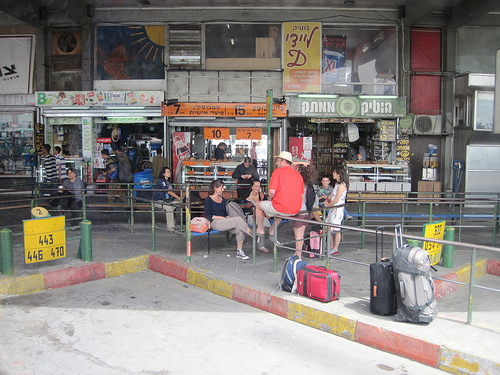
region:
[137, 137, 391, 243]
People at a bus terminal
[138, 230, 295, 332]
The parking curb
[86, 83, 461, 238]
Stores at the bus terminal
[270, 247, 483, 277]
Some luggage on the curb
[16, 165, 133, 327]
A sign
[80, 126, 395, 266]
People sitting on the bench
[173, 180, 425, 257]
Waiting to travel on a bus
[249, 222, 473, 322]
Four bags of luggage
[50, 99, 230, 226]
People on the sidewalks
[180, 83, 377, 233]
Stores with workers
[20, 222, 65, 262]
Yellow sign with numbers on it on the left side.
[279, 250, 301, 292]
Blue and white back pack on the sidewalk.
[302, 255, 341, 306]
Red and black suitcase on the sidewalk.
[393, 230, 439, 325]
Gray rolling suitcase on the sidewalk.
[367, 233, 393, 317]
Black rolling suitcase on the sidewalk.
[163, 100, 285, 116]
Long orange business sign.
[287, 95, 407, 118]
Green business sign.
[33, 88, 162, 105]
White long business sign with different colors.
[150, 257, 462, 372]
Yellow and red curb in front of the sidewalk where the bags are placed.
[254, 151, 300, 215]
Guy in the red t-shirt.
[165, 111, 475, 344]
people waiting outdoors with luggage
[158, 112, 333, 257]
people waiting on seats in front os small shops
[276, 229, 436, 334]
four pieces of luggage near curb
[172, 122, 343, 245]
group of travelers talking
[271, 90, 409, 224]
small shop to help travelers with needs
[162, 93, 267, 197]
shop with orange signs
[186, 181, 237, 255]
woman with navy blue shirt on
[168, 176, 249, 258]
woman with purse next to her on bench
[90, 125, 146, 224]
people hurrying with luggage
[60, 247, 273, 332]
corner of curb with red and yellow paint is quite worn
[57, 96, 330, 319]
People at a bus station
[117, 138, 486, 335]
People waiting for the bus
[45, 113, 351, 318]
People traveling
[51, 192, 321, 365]
The curb on the bus terminal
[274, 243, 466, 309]
Four luggage on the curb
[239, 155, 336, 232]
A guy sitting on the rail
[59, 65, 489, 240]
Stores along the walkway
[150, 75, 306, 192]
The store front at the bus station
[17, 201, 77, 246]
A sign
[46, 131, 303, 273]
People sitting on the benches waiting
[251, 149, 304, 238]
a man sitting on a metal rail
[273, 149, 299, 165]
a man with a white hat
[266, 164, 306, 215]
a man with a orange shirt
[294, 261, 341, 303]
a red and black luggage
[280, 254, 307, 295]
a blue and white carrying bag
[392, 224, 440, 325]
a dark and light gray rolling bag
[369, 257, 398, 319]
a black and orange tow bag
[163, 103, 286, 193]
a small food stand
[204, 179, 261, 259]
a women with her legs cross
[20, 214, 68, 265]
a yellow and black sign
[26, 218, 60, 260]
yellow and black sign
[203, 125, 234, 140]
orange and black sign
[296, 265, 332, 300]
a red suitcase on the ground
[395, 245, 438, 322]
a large grey suitcase